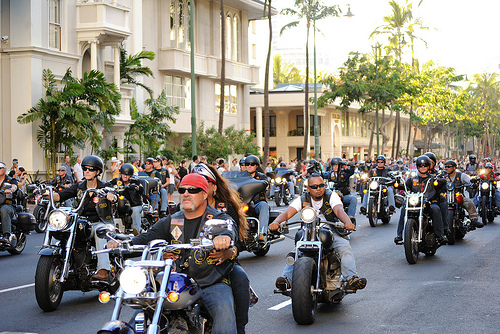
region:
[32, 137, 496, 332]
motorcycle gang on bikes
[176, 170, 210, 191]
red bandana head of motor cycle member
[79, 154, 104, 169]
black helmet of other motorcycle member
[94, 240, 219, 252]
handle bars on bike in front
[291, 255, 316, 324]
wheel of bike behind the front bike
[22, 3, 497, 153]
treeson side walk behind bikers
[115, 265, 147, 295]
headlight on bike in front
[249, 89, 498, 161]
building behind trees and bikers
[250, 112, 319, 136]
windows in building in background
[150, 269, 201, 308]
gas tank on bike in front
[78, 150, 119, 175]
head of a person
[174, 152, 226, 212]
head of a person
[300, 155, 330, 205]
head of a person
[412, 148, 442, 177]
head of a person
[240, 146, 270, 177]
head of a person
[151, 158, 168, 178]
head of a person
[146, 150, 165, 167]
head of a person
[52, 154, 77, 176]
head of a person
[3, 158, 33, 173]
head of a person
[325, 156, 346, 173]
head of a person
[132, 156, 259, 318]
this is a man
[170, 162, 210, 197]
man wearing a scarf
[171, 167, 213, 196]
the scarf is red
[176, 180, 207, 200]
pair of black sunglasses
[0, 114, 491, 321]
a group of people on motorcycles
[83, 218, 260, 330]
this is a motorcycle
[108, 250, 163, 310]
headlight on the motorcycle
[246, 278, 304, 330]
white line on road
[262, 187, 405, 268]
man wearing a vest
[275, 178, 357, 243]
man wearing a white shirt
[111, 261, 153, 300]
Headlight on the motorcycle.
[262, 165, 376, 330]
Man on the motorcycle.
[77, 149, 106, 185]
Helmet on the man.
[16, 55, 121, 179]
Palm tree by the window.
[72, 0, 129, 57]
Balcony on the building.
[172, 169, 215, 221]
Sunglasses on the man.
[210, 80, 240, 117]
Window in the building.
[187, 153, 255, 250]
Long hair on the woman.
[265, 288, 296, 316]
White line on the pavement.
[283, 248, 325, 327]
Black tire on the front.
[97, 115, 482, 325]
people riding on motorcycle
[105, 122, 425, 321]
motorcyclist driving togehter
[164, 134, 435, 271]
poeple driving motorcycles in a group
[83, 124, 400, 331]
people driving motorcyles in a group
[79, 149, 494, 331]
people drivin gmotorcycles on the road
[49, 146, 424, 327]
people driving motorcycles on teh street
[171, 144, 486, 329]
a road with motorcycles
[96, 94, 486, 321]
a street with motorcycles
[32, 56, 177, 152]
leaves on a tree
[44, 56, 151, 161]
green leaves on teh tree